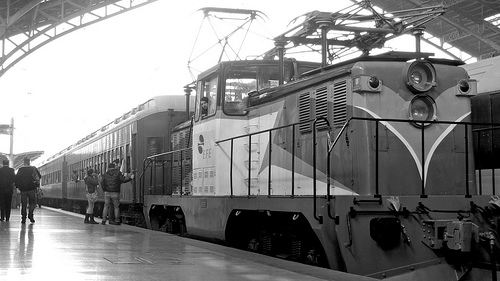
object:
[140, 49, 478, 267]
train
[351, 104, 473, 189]
v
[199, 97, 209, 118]
passenger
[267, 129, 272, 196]
rail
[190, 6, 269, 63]
beams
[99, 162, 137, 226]
people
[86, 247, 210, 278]
platform